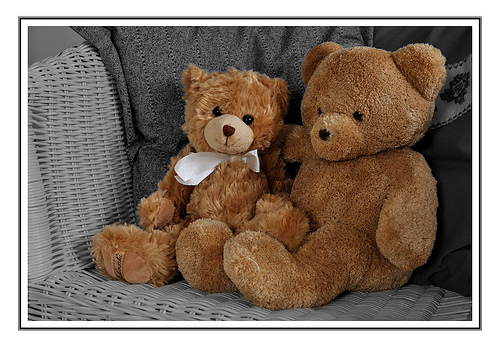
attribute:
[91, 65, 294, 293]
teddy bear — little, shaggy, brown, plush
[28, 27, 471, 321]
chair — wicker, white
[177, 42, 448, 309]
teddy bear — brown, plush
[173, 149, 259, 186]
bow — white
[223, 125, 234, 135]
nose — brown, black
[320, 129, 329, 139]
nose — brown, black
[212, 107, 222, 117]
eye — black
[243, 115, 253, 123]
eye — black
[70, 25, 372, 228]
blanket — grey, gray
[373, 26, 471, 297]
blanket — grey, gray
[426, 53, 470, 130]
trim — white, lace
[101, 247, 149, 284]
pad — cloth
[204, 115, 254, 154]
nose — white, tan, brown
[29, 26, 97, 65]
wall — white